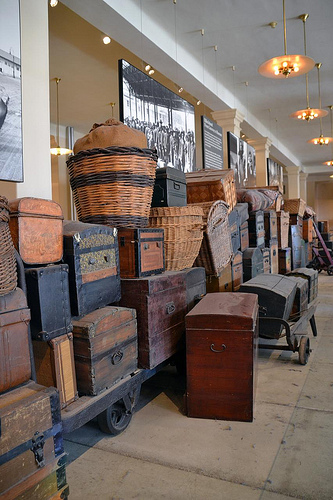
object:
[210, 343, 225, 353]
handle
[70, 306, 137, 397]
box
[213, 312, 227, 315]
brown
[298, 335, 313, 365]
wheel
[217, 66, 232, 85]
ceiling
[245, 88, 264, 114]
ceiling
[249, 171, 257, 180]
wall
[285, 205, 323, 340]
distance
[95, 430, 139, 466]
floor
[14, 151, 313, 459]
pile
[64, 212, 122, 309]
trunk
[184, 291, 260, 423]
box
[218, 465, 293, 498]
lines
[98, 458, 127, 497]
pavement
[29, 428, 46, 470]
clasp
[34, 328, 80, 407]
suitcase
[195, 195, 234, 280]
basket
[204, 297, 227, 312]
dust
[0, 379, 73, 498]
trunk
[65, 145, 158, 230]
basket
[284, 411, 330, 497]
ground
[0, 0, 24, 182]
picture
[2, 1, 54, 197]
wall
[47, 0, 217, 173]
wall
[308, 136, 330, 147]
light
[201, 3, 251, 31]
ceiling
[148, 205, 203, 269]
basket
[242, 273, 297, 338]
trunk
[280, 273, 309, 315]
trunk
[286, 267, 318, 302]
trunk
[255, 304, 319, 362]
cart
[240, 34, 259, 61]
ceiling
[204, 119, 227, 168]
white words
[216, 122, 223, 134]
black surface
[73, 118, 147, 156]
bag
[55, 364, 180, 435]
cart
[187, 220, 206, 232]
handle